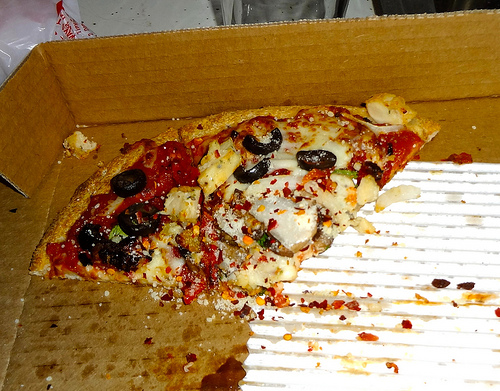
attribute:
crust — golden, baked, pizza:
[28, 103, 440, 273]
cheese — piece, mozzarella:
[247, 193, 319, 253]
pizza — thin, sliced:
[23, 95, 445, 303]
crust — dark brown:
[175, 103, 449, 141]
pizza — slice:
[170, 101, 439, 291]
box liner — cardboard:
[243, 160, 498, 388]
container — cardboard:
[1, 6, 498, 388]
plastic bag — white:
[4, 1, 99, 54]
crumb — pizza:
[60, 126, 100, 162]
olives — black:
[31, 86, 362, 303]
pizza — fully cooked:
[31, 86, 495, 370]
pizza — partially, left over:
[82, 157, 257, 284]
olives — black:
[225, 126, 305, 196]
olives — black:
[95, 160, 160, 275]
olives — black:
[108, 166, 147, 195]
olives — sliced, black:
[235, 129, 328, 183]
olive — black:
[302, 149, 336, 168]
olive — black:
[237, 161, 269, 174]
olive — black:
[248, 132, 285, 148]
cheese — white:
[203, 122, 356, 251]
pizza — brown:
[33, 100, 443, 315]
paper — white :
[349, 193, 451, 295]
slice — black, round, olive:
[107, 167, 147, 192]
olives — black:
[113, 158, 146, 256]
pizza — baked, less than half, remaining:
[27, 89, 442, 288]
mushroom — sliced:
[363, 90, 415, 124]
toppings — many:
[104, 157, 390, 320]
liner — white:
[238, 147, 483, 359]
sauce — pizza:
[383, 134, 421, 170]